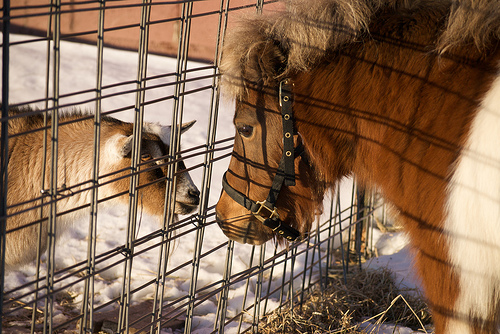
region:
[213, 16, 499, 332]
A brown and white pony.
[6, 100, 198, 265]
A tan and white goat.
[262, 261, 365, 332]
Straw on the ground for the pony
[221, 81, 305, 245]
Pony has his halter gear on.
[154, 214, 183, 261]
Goat has a beard.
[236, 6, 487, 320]
Shadows are falling across the pony.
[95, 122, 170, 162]
The goat has white spots behind his ears.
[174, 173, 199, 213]
The goat has a white muzzle.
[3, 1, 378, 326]
the metal fence seperating the animals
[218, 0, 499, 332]
a shetland pony standing and looking at the goat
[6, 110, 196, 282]
the goat checking out the horse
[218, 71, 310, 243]
the bridle on the horses head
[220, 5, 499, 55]
the mane on the horses neck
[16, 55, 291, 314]
the snow on the ground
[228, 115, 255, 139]
the eye of the horse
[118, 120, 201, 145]
the big ears of the goat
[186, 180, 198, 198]
the nose of the goat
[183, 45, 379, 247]
the head of a horse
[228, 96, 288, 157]
the eye of a horse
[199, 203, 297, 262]
the mouth of a horse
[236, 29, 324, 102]
the ear of a horse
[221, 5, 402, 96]
the main of a horse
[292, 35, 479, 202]
the neck of a horse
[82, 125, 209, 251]
the head of a goat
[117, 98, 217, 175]
the ears of a goat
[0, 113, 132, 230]
the neck of a goat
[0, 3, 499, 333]
two animals on either side of the fence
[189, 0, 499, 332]
brown and white pony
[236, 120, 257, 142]
eye on the side of the head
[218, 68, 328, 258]
black straps around the face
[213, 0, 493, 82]
thick hair running along the neck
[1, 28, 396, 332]
snow on the ground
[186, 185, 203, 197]
small nose on the tip of the snout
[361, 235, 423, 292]
shadows on the ground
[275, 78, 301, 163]
holes in the strap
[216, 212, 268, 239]
shadow on the animal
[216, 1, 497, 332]
The horse is hairy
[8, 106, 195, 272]
A hairy little goat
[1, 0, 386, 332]
Fence made of metal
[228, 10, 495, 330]
Shadow from the fence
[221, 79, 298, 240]
The reigns are black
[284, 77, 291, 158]
Some brass colored holes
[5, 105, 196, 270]
Goat is brown and white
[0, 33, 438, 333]
Snow on the ground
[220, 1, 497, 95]
Mane is light brown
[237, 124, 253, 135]
The eye is black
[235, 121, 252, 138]
eye belongs to animal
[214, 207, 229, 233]
nostril belongs to animal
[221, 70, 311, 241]
harness worn by animal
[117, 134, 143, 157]
ear belongs to animal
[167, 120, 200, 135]
ear belongs to animal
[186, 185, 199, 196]
nose belongs to animal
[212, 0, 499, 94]
mane belongs to animal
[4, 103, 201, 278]
animal looks at animal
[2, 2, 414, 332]
fence separates animals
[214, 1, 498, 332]
pony has black halter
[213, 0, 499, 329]
pony is brown and white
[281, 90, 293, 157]
four gromets on halter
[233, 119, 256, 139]
left eye of pony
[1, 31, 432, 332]
snow on ground